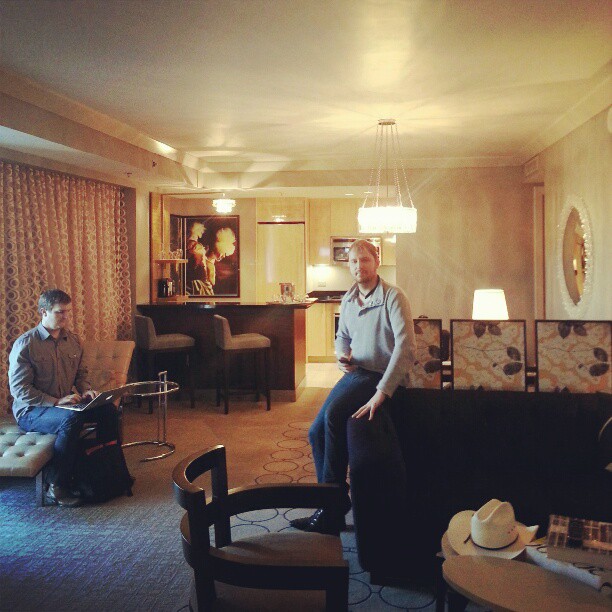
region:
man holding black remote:
[296, 229, 423, 532]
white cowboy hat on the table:
[437, 494, 550, 570]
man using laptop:
[11, 286, 143, 501]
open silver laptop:
[59, 380, 132, 414]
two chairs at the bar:
[132, 302, 278, 413]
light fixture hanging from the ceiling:
[354, 115, 423, 239]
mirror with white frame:
[543, 195, 591, 306]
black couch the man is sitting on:
[352, 370, 610, 602]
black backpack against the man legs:
[62, 412, 141, 505]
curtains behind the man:
[6, 166, 144, 401]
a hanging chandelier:
[350, 108, 421, 233]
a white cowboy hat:
[440, 496, 544, 561]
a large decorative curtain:
[0, 173, 137, 357]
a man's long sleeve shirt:
[11, 322, 101, 415]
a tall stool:
[211, 308, 277, 414]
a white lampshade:
[472, 287, 510, 318]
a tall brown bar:
[131, 293, 312, 401]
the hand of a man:
[347, 395, 387, 421]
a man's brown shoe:
[41, 482, 86, 507]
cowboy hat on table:
[432, 490, 541, 561]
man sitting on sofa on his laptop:
[0, 283, 119, 487]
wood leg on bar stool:
[256, 339, 270, 405]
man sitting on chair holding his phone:
[306, 236, 410, 496]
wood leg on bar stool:
[174, 343, 196, 408]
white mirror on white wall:
[550, 198, 580, 300]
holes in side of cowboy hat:
[498, 514, 517, 541]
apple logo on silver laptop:
[93, 384, 130, 410]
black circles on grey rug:
[257, 457, 301, 484]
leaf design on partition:
[420, 358, 439, 378]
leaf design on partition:
[425, 344, 439, 358]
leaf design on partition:
[411, 322, 423, 334]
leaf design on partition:
[502, 359, 523, 375]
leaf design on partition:
[474, 316, 487, 336]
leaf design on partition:
[485, 322, 504, 337]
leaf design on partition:
[557, 315, 576, 343]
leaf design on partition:
[570, 322, 586, 343]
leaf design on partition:
[587, 361, 607, 383]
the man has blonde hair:
[258, 204, 421, 544]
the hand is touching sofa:
[344, 359, 430, 447]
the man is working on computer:
[0, 268, 152, 507]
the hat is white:
[432, 480, 554, 580]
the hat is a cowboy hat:
[441, 478, 552, 568]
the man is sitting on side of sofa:
[255, 218, 414, 537]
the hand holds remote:
[318, 331, 369, 376]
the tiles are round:
[260, 418, 297, 482]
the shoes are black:
[273, 496, 344, 547]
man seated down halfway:
[277, 209, 425, 538]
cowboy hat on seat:
[445, 492, 534, 565]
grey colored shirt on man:
[318, 274, 422, 402]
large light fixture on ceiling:
[339, 112, 421, 237]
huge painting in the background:
[176, 195, 240, 297]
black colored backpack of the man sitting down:
[61, 399, 140, 509]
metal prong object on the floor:
[120, 357, 182, 467]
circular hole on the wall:
[546, 190, 600, 310]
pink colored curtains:
[0, 170, 128, 344]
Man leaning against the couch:
[292, 240, 415, 531]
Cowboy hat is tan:
[444, 498, 539, 562]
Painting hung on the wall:
[186, 217, 242, 299]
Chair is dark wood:
[175, 444, 353, 601]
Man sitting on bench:
[12, 286, 123, 503]